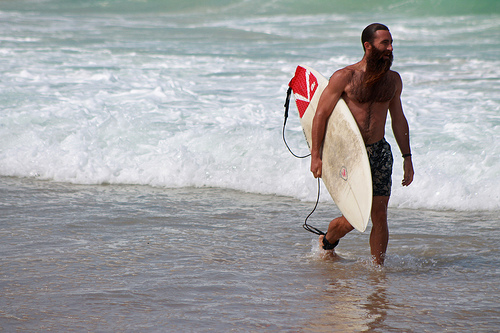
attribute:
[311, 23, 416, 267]
man — walking, shirtless, barefoot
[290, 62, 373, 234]
surfboard — white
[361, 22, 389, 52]
hair — short, brown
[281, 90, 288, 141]
wire — black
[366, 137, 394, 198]
shorts — black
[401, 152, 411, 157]
band — black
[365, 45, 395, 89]
beard — long, wet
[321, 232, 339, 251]
band — black, strapped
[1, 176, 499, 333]
beach — calm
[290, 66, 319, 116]
logo — red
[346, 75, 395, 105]
chest — hairy